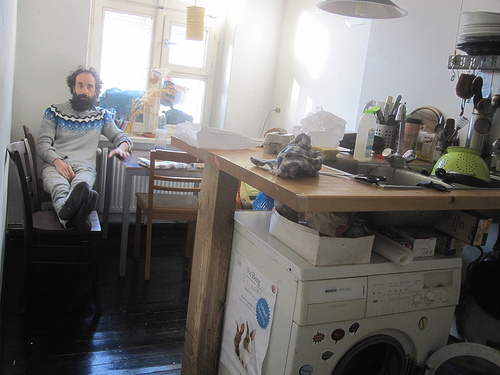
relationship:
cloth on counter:
[245, 126, 328, 190] [154, 122, 493, 374]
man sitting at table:
[40, 67, 124, 229] [107, 125, 249, 273]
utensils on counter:
[362, 95, 408, 158] [169, 132, 498, 212]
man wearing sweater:
[36, 65, 134, 234] [40, 104, 124, 181]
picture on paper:
[220, 318, 267, 365] [218, 247, 278, 373]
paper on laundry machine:
[218, 247, 278, 373] [221, 207, 464, 373]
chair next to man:
[130, 130, 223, 286] [36, 65, 134, 234]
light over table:
[185, 4, 205, 41] [98, 146, 202, 277]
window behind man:
[90, 0, 238, 145] [36, 65, 134, 234]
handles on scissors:
[353, 168, 390, 189] [314, 166, 391, 189]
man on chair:
[36, 65, 134, 234] [3, 123, 103, 309]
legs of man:
[39, 150, 99, 227] [36, 65, 134, 234]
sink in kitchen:
[311, 146, 452, 190] [196, 97, 495, 370]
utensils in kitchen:
[359, 93, 411, 163] [196, 97, 495, 370]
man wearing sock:
[36, 65, 134, 234] [61, 182, 88, 220]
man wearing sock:
[36, 65, 134, 234] [66, 188, 96, 230]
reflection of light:
[292, 12, 366, 122] [192, 0, 431, 179]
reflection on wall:
[292, 12, 366, 122] [267, 4, 489, 174]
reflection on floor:
[69, 291, 134, 350] [8, 315, 176, 374]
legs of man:
[39, 167, 99, 207] [36, 65, 134, 234]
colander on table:
[431, 144, 493, 184] [175, 93, 497, 233]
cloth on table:
[250, 133, 325, 177] [201, 130, 497, 218]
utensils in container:
[362, 95, 408, 158] [371, 121, 399, 152]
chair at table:
[133, 148, 205, 280] [100, 127, 205, 274]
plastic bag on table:
[174, 116, 266, 156] [297, 192, 375, 205]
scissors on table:
[342, 168, 384, 193] [291, 182, 359, 200]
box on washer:
[269, 208, 379, 266] [220, 209, 500, 375]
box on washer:
[391, 225, 437, 252] [220, 209, 500, 375]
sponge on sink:
[309, 140, 344, 164] [315, 96, 488, 188]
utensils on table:
[436, 100, 476, 177] [333, 176, 415, 205]